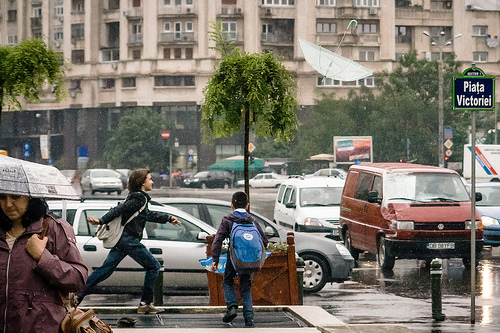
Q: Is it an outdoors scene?
A: Yes, it is outdoors.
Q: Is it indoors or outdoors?
A: It is outdoors.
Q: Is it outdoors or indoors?
A: It is outdoors.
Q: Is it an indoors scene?
A: No, it is outdoors.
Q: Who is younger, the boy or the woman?
A: The boy is younger than the woman.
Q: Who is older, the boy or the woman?
A: The woman is older than the boy.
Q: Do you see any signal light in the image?
A: No, there are no traffic lights.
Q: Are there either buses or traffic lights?
A: No, there are no traffic lights or buses.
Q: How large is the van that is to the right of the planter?
A: The van is large.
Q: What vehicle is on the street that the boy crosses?
A: The vehicle is a van.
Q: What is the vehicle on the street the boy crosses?
A: The vehicle is a van.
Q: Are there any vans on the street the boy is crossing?
A: Yes, there is a van on the street.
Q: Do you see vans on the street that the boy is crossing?
A: Yes, there is a van on the street.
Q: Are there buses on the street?
A: No, there is a van on the street.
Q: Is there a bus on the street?
A: No, there is a van on the street.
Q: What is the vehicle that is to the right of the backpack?
A: The vehicle is a van.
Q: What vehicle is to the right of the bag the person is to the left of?
A: The vehicle is a van.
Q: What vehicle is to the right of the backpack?
A: The vehicle is a van.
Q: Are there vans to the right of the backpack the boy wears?
A: Yes, there is a van to the right of the backpack.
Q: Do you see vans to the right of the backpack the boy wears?
A: Yes, there is a van to the right of the backpack.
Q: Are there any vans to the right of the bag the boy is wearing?
A: Yes, there is a van to the right of the backpack.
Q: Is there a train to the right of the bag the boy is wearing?
A: No, there is a van to the right of the backpack.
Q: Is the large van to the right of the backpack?
A: Yes, the van is to the right of the backpack.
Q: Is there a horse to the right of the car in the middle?
A: No, there is a van to the right of the car.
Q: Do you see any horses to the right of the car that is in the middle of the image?
A: No, there is a van to the right of the car.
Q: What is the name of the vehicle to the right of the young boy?
A: The vehicle is a van.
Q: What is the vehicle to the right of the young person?
A: The vehicle is a van.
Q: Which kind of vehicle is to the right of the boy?
A: The vehicle is a van.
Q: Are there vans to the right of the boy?
A: Yes, there is a van to the right of the boy.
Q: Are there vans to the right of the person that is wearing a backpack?
A: Yes, there is a van to the right of the boy.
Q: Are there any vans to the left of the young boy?
A: No, the van is to the right of the boy.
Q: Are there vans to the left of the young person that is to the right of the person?
A: No, the van is to the right of the boy.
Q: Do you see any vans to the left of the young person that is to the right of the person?
A: No, the van is to the right of the boy.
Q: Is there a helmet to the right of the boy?
A: No, there is a van to the right of the boy.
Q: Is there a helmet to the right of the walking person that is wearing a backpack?
A: No, there is a van to the right of the boy.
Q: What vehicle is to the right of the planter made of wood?
A: The vehicle is a van.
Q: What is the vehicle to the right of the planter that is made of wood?
A: The vehicle is a van.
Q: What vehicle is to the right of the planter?
A: The vehicle is a van.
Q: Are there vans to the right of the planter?
A: Yes, there is a van to the right of the planter.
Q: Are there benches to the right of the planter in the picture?
A: No, there is a van to the right of the planter.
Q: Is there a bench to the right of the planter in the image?
A: No, there is a van to the right of the planter.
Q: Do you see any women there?
A: Yes, there is a woman.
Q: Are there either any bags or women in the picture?
A: Yes, there is a woman.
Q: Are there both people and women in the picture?
A: Yes, there are both a woman and a person.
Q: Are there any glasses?
A: No, there are no glasses.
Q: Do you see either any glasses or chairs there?
A: No, there are no glasses or chairs.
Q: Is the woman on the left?
A: Yes, the woman is on the left of the image.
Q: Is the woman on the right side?
A: No, the woman is on the left of the image.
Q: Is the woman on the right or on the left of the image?
A: The woman is on the left of the image.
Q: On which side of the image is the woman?
A: The woman is on the left of the image.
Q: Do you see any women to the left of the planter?
A: Yes, there is a woman to the left of the planter.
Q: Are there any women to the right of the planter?
A: No, the woman is to the left of the planter.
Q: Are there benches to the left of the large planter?
A: No, there is a woman to the left of the planter.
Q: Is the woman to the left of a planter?
A: Yes, the woman is to the left of a planter.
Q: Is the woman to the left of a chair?
A: No, the woman is to the left of a planter.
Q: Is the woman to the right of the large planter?
A: No, the woman is to the left of the planter.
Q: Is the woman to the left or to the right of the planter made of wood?
A: The woman is to the left of the planter.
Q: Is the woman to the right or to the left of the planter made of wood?
A: The woman is to the left of the planter.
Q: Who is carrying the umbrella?
A: The woman is carrying the umbrella.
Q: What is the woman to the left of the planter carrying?
A: The woman is carrying an umbrella.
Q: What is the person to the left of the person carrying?
A: The woman is carrying an umbrella.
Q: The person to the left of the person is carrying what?
A: The woman is carrying an umbrella.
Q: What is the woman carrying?
A: The woman is carrying an umbrella.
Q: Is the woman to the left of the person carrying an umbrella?
A: Yes, the woman is carrying an umbrella.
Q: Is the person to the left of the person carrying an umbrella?
A: Yes, the woman is carrying an umbrella.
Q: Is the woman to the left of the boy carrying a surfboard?
A: No, the woman is carrying an umbrella.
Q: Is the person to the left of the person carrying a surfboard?
A: No, the woman is carrying an umbrella.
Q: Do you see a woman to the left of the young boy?
A: Yes, there is a woman to the left of the boy.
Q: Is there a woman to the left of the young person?
A: Yes, there is a woman to the left of the boy.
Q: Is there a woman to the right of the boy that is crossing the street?
A: No, the woman is to the left of the boy.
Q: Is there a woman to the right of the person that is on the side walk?
A: No, the woman is to the left of the boy.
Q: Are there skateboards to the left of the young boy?
A: No, there is a woman to the left of the boy.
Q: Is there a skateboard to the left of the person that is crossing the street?
A: No, there is a woman to the left of the boy.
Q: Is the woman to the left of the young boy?
A: Yes, the woman is to the left of the boy.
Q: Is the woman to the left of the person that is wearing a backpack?
A: Yes, the woman is to the left of the boy.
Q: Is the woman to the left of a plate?
A: No, the woman is to the left of the boy.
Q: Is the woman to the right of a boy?
A: No, the woman is to the left of a boy.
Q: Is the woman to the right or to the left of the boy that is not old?
A: The woman is to the left of the boy.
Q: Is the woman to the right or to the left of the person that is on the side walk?
A: The woman is to the left of the boy.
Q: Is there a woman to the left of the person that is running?
A: Yes, there is a woman to the left of the person.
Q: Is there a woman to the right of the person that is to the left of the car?
A: No, the woman is to the left of the person.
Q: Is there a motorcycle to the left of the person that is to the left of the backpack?
A: No, there is a woman to the left of the person.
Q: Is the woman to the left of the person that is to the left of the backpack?
A: Yes, the woman is to the left of the person.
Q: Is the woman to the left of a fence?
A: No, the woman is to the left of the person.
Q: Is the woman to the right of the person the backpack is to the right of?
A: No, the woman is to the left of the person.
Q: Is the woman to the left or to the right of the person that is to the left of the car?
A: The woman is to the left of the person.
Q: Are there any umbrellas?
A: Yes, there is an umbrella.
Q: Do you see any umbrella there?
A: Yes, there is an umbrella.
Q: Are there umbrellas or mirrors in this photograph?
A: Yes, there is an umbrella.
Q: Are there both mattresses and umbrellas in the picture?
A: No, there is an umbrella but no mattresses.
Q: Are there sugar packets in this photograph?
A: No, there are no sugar packets.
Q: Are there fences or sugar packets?
A: No, there are no sugar packets or fences.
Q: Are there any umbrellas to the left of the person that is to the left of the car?
A: Yes, there is an umbrella to the left of the person.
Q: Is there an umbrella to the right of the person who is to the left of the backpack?
A: No, the umbrella is to the left of the person.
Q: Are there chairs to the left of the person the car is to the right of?
A: No, there is an umbrella to the left of the person.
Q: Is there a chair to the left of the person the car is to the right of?
A: No, there is an umbrella to the left of the person.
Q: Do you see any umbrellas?
A: Yes, there is an umbrella.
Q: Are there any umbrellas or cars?
A: Yes, there is an umbrella.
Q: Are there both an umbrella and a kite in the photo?
A: No, there is an umbrella but no kites.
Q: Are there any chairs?
A: No, there are no chairs.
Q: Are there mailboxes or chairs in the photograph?
A: No, there are no chairs or mailboxes.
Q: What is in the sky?
A: The umbrella is in the sky.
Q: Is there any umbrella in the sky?
A: Yes, there is an umbrella in the sky.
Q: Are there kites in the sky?
A: No, there is an umbrella in the sky.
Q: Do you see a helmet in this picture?
A: No, there are no helmets.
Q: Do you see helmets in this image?
A: No, there are no helmets.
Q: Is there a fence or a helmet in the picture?
A: No, there are no helmets or fences.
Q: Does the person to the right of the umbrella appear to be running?
A: Yes, the person is running.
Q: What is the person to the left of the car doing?
A: The person is running.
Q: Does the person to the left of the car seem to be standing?
A: No, the person is running.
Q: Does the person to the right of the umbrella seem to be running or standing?
A: The person is running.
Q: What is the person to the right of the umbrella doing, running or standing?
A: The person is running.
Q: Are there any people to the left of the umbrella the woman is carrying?
A: No, the person is to the right of the umbrella.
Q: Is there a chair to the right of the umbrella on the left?
A: No, there is a person to the right of the umbrella.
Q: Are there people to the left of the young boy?
A: Yes, there is a person to the left of the boy.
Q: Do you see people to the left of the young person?
A: Yes, there is a person to the left of the boy.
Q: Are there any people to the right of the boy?
A: No, the person is to the left of the boy.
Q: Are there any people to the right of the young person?
A: No, the person is to the left of the boy.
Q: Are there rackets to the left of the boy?
A: No, there is a person to the left of the boy.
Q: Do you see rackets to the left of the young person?
A: No, there is a person to the left of the boy.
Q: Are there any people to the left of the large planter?
A: Yes, there is a person to the left of the planter.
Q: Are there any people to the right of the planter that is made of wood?
A: No, the person is to the left of the planter.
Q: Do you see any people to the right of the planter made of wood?
A: No, the person is to the left of the planter.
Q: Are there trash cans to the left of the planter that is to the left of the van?
A: No, there is a person to the left of the planter.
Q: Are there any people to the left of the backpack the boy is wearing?
A: Yes, there is a person to the left of the backpack.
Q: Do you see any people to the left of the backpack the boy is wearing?
A: Yes, there is a person to the left of the backpack.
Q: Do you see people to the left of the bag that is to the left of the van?
A: Yes, there is a person to the left of the backpack.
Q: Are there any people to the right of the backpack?
A: No, the person is to the left of the backpack.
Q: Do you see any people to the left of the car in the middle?
A: Yes, there is a person to the left of the car.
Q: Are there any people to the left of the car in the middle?
A: Yes, there is a person to the left of the car.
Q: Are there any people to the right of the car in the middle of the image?
A: No, the person is to the left of the car.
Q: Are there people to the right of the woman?
A: Yes, there is a person to the right of the woman.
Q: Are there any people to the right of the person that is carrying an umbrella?
A: Yes, there is a person to the right of the woman.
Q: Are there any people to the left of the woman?
A: No, the person is to the right of the woman.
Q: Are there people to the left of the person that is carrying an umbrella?
A: No, the person is to the right of the woman.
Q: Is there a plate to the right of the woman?
A: No, there is a person to the right of the woman.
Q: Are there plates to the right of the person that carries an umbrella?
A: No, there is a person to the right of the woman.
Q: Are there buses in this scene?
A: No, there are no buses.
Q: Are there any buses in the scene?
A: No, there are no buses.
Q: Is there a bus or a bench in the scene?
A: No, there are no buses or benches.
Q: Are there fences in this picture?
A: No, there are no fences.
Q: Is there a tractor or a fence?
A: No, there are no fences or tractors.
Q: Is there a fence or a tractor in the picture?
A: No, there are no fences or tractors.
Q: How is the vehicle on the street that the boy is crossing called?
A: The vehicle is a van.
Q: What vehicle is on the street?
A: The vehicle is a van.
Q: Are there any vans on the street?
A: Yes, there is a van on the street.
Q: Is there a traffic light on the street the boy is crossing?
A: No, there is a van on the street.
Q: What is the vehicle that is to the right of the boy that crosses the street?
A: The vehicle is a van.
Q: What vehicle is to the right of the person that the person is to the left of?
A: The vehicle is a van.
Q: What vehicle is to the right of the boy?
A: The vehicle is a van.